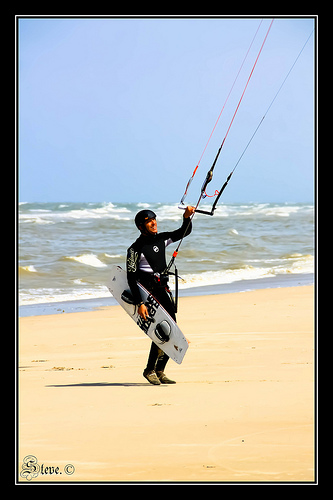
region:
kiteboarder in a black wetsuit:
[126, 204, 196, 384]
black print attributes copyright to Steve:
[20, 454, 74, 480]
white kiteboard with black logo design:
[104, 264, 189, 363]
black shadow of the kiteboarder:
[44, 381, 167, 387]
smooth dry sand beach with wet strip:
[17, 273, 314, 481]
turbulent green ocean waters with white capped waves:
[17, 201, 313, 303]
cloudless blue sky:
[17, 17, 313, 202]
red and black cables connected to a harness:
[153, 18, 314, 312]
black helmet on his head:
[134, 209, 157, 233]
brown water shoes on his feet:
[143, 369, 176, 387]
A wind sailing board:
[92, 264, 201, 367]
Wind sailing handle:
[181, 61, 267, 201]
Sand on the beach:
[67, 353, 269, 457]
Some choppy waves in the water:
[44, 202, 225, 272]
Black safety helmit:
[116, 199, 157, 238]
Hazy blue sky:
[55, 70, 150, 136]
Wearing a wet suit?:
[84, 157, 212, 387]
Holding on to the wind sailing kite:
[111, 187, 219, 376]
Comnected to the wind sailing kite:
[139, 229, 228, 289]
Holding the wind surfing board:
[100, 262, 238, 365]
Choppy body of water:
[22, 195, 309, 323]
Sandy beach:
[26, 300, 293, 417]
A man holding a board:
[107, 203, 191, 391]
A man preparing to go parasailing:
[113, 175, 226, 391]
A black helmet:
[132, 208, 157, 227]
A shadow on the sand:
[39, 367, 161, 390]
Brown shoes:
[140, 366, 176, 389]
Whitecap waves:
[34, 201, 135, 223]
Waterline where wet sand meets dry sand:
[182, 281, 311, 300]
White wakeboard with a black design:
[99, 263, 191, 364]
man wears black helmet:
[124, 207, 162, 230]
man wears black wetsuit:
[126, 224, 170, 370]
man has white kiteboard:
[97, 265, 187, 376]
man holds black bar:
[163, 167, 216, 255]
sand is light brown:
[31, 313, 301, 496]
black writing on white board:
[103, 261, 186, 353]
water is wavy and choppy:
[39, 195, 319, 321]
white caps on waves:
[47, 199, 315, 301]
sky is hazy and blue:
[38, 88, 302, 203]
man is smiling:
[134, 214, 153, 248]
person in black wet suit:
[95, 170, 199, 394]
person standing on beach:
[94, 306, 244, 433]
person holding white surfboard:
[74, 206, 229, 386]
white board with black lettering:
[93, 234, 194, 358]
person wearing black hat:
[119, 190, 158, 232]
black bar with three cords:
[118, 61, 234, 226]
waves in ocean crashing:
[30, 184, 293, 298]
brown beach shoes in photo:
[138, 365, 182, 388]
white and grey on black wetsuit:
[128, 243, 161, 282]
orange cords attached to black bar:
[189, 106, 248, 239]